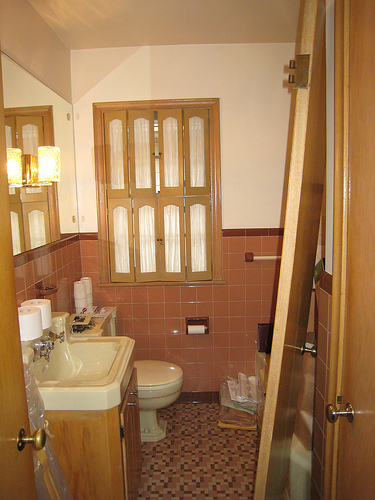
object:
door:
[251, 0, 325, 499]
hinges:
[283, 55, 309, 89]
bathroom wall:
[77, 234, 277, 389]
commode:
[128, 359, 184, 442]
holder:
[186, 324, 207, 335]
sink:
[25, 336, 136, 410]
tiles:
[178, 280, 228, 317]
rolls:
[18, 299, 52, 341]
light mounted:
[25, 145, 61, 186]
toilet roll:
[16, 307, 43, 342]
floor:
[134, 401, 290, 499]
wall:
[0, 241, 80, 310]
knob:
[301, 344, 318, 357]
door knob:
[17, 428, 46, 451]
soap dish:
[40, 284, 58, 296]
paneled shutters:
[101, 107, 213, 282]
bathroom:
[1, 2, 370, 500]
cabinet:
[38, 341, 142, 499]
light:
[38, 146, 61, 183]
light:
[5, 148, 23, 187]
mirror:
[0, 51, 80, 256]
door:
[330, 0, 372, 499]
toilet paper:
[188, 325, 206, 335]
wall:
[69, 44, 294, 402]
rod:
[245, 251, 282, 262]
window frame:
[93, 100, 218, 289]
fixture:
[24, 146, 62, 188]